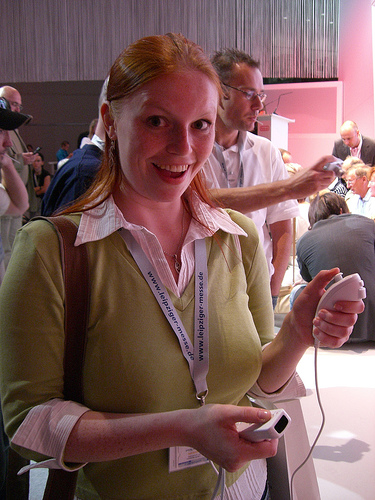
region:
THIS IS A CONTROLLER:
[229, 268, 367, 486]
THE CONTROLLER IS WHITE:
[234, 265, 365, 454]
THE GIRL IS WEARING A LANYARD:
[105, 226, 220, 401]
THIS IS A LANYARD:
[115, 226, 224, 396]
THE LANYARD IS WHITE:
[111, 219, 233, 406]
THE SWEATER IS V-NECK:
[0, 191, 275, 497]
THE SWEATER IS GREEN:
[0, 201, 283, 497]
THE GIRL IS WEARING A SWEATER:
[0, 197, 291, 497]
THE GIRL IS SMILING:
[142, 156, 199, 190]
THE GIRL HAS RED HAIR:
[59, 23, 238, 221]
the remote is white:
[306, 265, 372, 351]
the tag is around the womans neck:
[154, 309, 226, 398]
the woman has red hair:
[125, 44, 165, 79]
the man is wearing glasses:
[229, 76, 270, 105]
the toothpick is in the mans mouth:
[245, 109, 266, 131]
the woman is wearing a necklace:
[160, 235, 181, 271]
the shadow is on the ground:
[326, 429, 367, 467]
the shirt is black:
[298, 214, 373, 264]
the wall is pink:
[342, 16, 370, 82]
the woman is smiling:
[1, 26, 355, 477]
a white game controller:
[312, 260, 368, 352]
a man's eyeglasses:
[218, 80, 268, 106]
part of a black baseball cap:
[0, 96, 37, 130]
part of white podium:
[258, 111, 294, 150]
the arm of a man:
[197, 177, 288, 211]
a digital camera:
[323, 157, 345, 178]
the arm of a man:
[263, 153, 298, 301]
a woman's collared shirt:
[0, 189, 307, 498]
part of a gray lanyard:
[213, 142, 245, 189]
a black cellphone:
[31, 144, 42, 155]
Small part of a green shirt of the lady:
[100, 331, 164, 363]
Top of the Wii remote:
[271, 407, 294, 432]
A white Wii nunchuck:
[324, 273, 365, 299]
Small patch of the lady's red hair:
[139, 47, 162, 64]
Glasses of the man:
[243, 89, 270, 102]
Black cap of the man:
[0, 99, 31, 126]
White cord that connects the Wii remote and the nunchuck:
[307, 395, 336, 445]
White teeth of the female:
[168, 165, 185, 174]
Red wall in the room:
[353, 32, 365, 54]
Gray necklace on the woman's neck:
[170, 250, 181, 273]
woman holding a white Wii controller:
[16, 21, 352, 477]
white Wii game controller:
[251, 261, 359, 467]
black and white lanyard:
[110, 208, 238, 466]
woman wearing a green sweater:
[15, 83, 280, 478]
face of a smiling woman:
[99, 80, 230, 213]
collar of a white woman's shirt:
[76, 181, 243, 295]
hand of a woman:
[290, 261, 366, 358]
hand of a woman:
[188, 393, 297, 471]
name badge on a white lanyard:
[119, 205, 220, 478]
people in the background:
[229, 88, 368, 216]